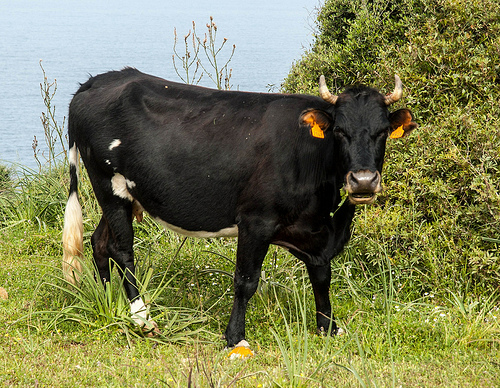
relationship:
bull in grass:
[59, 68, 413, 353] [6, 170, 499, 383]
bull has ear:
[59, 68, 413, 353] [297, 103, 331, 139]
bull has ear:
[59, 68, 413, 353] [389, 105, 416, 141]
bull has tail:
[59, 68, 413, 353] [62, 113, 78, 284]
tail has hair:
[62, 113, 78, 284] [57, 192, 84, 285]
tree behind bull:
[272, 3, 499, 295] [59, 68, 413, 353]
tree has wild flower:
[272, 3, 499, 295] [400, 39, 423, 59]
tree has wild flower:
[272, 3, 499, 295] [448, 135, 475, 166]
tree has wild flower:
[272, 3, 499, 295] [478, 168, 499, 205]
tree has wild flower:
[272, 3, 499, 295] [422, 285, 458, 347]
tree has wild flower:
[272, 3, 499, 295] [467, 252, 498, 275]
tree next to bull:
[272, 3, 499, 295] [59, 68, 413, 353]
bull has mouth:
[59, 68, 413, 353] [343, 183, 380, 203]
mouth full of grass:
[343, 183, 380, 203] [6, 170, 499, 383]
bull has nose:
[59, 68, 413, 353] [350, 171, 379, 192]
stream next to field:
[2, 2, 325, 203] [4, 4, 497, 387]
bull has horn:
[59, 68, 413, 353] [385, 71, 404, 107]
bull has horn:
[59, 68, 413, 353] [318, 73, 343, 104]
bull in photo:
[59, 68, 413, 353] [3, 1, 499, 385]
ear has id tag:
[297, 103, 331, 139] [313, 115, 326, 138]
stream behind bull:
[2, 2, 325, 203] [59, 68, 413, 353]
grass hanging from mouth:
[331, 188, 350, 214] [343, 183, 380, 203]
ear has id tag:
[389, 105, 416, 141] [391, 115, 409, 135]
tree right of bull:
[272, 3, 499, 295] [59, 68, 413, 353]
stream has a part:
[2, 2, 325, 203] [256, 12, 293, 71]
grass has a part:
[6, 170, 499, 383] [28, 265, 61, 342]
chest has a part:
[280, 159, 344, 252] [299, 205, 317, 251]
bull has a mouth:
[59, 68, 413, 353] [343, 183, 380, 203]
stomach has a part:
[132, 178, 241, 229] [178, 201, 216, 209]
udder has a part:
[128, 201, 144, 230] [137, 207, 140, 216]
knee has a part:
[234, 270, 258, 303] [246, 288, 253, 294]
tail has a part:
[62, 113, 78, 284] [71, 147, 72, 162]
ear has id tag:
[389, 105, 416, 141] [313, 115, 326, 138]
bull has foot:
[59, 68, 413, 353] [132, 295, 157, 333]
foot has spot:
[132, 295, 157, 333] [132, 299, 154, 332]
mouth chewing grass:
[343, 183, 380, 203] [331, 188, 350, 214]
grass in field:
[6, 170, 499, 383] [4, 4, 497, 387]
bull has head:
[59, 68, 413, 353] [328, 88, 390, 207]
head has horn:
[328, 88, 390, 207] [385, 71, 404, 107]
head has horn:
[328, 88, 390, 207] [318, 73, 343, 104]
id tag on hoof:
[227, 347, 250, 354] [226, 335, 256, 354]